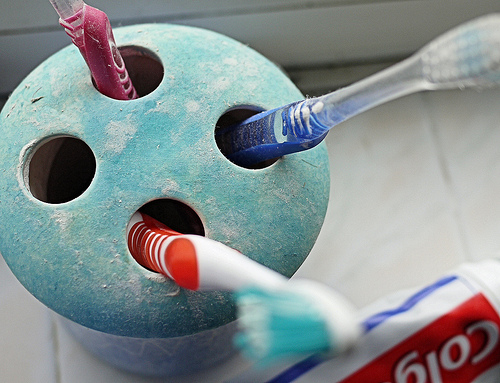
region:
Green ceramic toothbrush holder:
[0, 20, 330, 340]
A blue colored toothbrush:
[237, 12, 498, 155]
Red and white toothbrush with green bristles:
[125, 211, 362, 362]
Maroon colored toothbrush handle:
[49, 0, 139, 100]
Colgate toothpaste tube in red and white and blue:
[268, 259, 497, 380]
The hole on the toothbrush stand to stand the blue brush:
[213, 105, 281, 170]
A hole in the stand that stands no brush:
[19, 128, 96, 204]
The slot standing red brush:
[126, 196, 204, 273]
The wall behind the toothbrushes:
[2, 88, 497, 380]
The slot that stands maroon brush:
[87, 43, 163, 102]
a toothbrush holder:
[12, 17, 335, 379]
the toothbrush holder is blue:
[0, 19, 362, 369]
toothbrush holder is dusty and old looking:
[0, 18, 328, 360]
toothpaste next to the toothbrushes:
[271, 260, 498, 377]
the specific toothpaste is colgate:
[271, 261, 497, 376]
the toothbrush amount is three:
[60, 6, 492, 337]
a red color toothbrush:
[120, 207, 365, 358]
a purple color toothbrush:
[41, 0, 154, 90]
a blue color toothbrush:
[217, 13, 499, 153]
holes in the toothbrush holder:
[8, 44, 304, 249]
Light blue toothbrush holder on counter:
[3, 28, 352, 343]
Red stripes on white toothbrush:
[130, 218, 199, 289]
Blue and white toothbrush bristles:
[231, 284, 330, 367]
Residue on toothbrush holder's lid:
[98, 105, 208, 188]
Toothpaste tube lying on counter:
[263, 255, 498, 381]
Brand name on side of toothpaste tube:
[349, 318, 496, 382]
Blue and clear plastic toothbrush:
[222, 13, 499, 166]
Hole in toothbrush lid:
[19, 129, 98, 206]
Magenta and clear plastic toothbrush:
[51, 1, 141, 100]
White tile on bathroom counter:
[294, 65, 499, 308]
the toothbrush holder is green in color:
[6, 27, 329, 376]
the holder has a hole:
[16, 130, 100, 209]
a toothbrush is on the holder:
[126, 213, 356, 365]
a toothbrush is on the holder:
[228, 14, 495, 166]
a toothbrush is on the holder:
[43, 0, 137, 98]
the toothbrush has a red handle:
[61, 8, 140, 97]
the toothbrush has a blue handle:
[227, 99, 327, 161]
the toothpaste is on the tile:
[269, 258, 496, 380]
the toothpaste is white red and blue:
[258, 266, 493, 381]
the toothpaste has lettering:
[397, 323, 494, 379]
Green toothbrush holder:
[7, 18, 316, 382]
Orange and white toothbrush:
[132, 208, 356, 360]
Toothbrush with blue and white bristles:
[232, 278, 334, 368]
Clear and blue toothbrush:
[229, 12, 491, 164]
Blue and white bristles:
[424, 6, 499, 105]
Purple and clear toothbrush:
[49, 2, 146, 104]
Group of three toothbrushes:
[39, 3, 499, 348]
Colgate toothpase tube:
[348, 266, 498, 381]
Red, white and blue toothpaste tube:
[342, 268, 495, 380]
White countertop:
[333, 143, 495, 261]